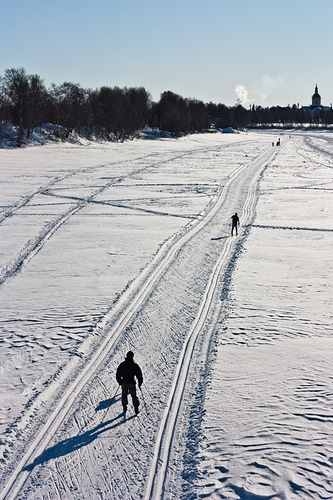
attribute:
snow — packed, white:
[34, 185, 298, 378]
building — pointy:
[298, 83, 329, 119]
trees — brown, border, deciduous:
[8, 88, 278, 137]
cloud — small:
[213, 77, 274, 115]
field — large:
[6, 153, 333, 480]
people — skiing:
[102, 206, 253, 423]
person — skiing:
[206, 206, 272, 265]